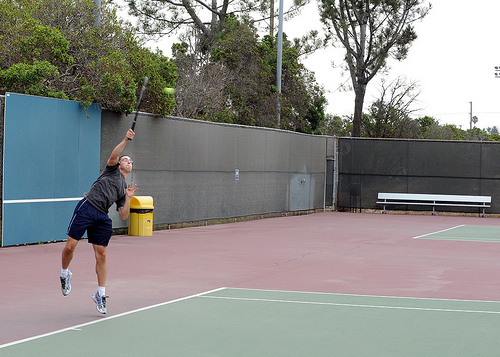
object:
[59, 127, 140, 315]
man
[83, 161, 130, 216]
tshirt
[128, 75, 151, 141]
racket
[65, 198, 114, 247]
shorts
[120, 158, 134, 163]
eyeglasses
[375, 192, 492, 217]
bench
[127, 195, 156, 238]
trashbin